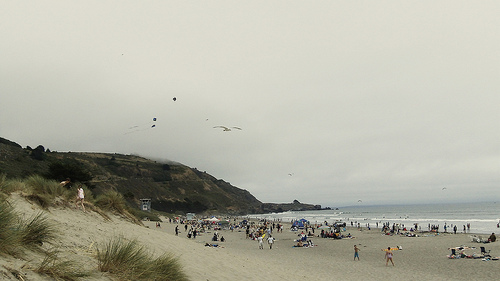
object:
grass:
[23, 173, 82, 203]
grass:
[34, 252, 83, 277]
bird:
[208, 123, 250, 133]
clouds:
[0, 0, 498, 204]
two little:
[346, 242, 401, 268]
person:
[351, 245, 364, 262]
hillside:
[60, 173, 249, 215]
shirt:
[264, 235, 275, 243]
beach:
[139, 213, 499, 280]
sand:
[1, 201, 498, 280]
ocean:
[232, 206, 500, 234]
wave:
[259, 213, 500, 226]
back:
[148, 116, 161, 123]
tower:
[139, 197, 156, 211]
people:
[74, 183, 91, 211]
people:
[257, 235, 265, 251]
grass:
[90, 235, 188, 280]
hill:
[0, 147, 263, 220]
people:
[487, 230, 499, 242]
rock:
[294, 198, 300, 205]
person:
[381, 245, 398, 266]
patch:
[31, 179, 70, 209]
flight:
[208, 124, 246, 133]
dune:
[0, 177, 221, 281]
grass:
[22, 213, 58, 246]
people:
[173, 224, 181, 238]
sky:
[2, 0, 500, 205]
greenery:
[0, 137, 263, 218]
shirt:
[76, 189, 85, 199]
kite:
[171, 96, 181, 102]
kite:
[147, 123, 157, 131]